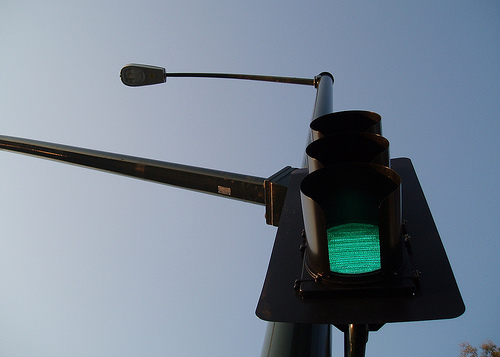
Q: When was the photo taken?
A: Daytime.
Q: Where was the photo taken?
A: On the street.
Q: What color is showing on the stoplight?
A: Green.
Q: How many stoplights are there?
A: One.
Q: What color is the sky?
A: Blue.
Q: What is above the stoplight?
A: Lamp post.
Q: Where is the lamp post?
A: Above the stoplight.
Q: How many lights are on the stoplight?
A: Three.